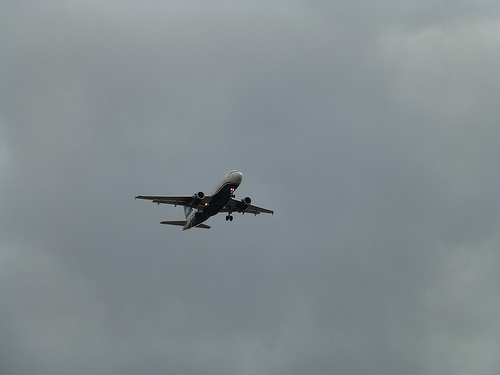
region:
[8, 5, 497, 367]
a plane on a cloudy sky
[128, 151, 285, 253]
the plane is in motion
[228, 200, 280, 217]
right wing of plane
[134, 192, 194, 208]
left wing of plane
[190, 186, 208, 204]
left engine of plane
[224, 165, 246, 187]
cockpit of plane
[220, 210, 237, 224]
wheels on right side of plane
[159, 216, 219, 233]
tail of plane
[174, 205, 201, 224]
vertical stabilizer of plane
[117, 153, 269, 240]
plane in the sky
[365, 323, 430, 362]
the sky is grey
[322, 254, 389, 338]
clouds in the sky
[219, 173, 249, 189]
front of the plane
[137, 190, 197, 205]
wing of the plane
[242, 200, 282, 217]
wing of the plane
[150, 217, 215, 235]
tail of the plane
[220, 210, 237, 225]
engine of the plane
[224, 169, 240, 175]
windshield of the plane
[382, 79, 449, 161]
white clouds in blue sky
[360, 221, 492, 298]
white clouds in blue sky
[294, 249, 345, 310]
white clouds in blue sky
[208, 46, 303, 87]
white clouds in blue sky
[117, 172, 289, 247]
plane in air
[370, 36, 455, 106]
white clouds in blue sky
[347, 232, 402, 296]
white clouds in blue sky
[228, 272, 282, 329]
white clouds in blue sky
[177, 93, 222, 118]
white clouds in blue sky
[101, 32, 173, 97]
white clouds in blue sky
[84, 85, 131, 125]
white clouds in blue sky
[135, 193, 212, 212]
Airplane wing that appears to look longer.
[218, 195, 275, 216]
Side grey airplane wing that appears smaller.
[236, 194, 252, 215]
Engine that is higher up.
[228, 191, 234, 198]
Landing gear under the nose.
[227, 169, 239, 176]
Windshields on the front of the plane.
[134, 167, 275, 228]
White and grey plane flying in the sky.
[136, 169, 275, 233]
Two engine flying airplane.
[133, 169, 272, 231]
White, blue and grey airplane.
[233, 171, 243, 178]
White nose of an airplane.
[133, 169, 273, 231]
An airplane flying in the sky.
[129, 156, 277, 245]
a plane that is flying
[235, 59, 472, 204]
a cloud that is grey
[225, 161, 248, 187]
the nose of a plane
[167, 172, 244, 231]
the body of a plane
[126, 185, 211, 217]
the right wing of a plane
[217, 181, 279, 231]
the left wing of a plane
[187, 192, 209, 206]
the turbine of a plane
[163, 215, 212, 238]
the back wings of a plane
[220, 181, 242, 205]
the wheels of a plane